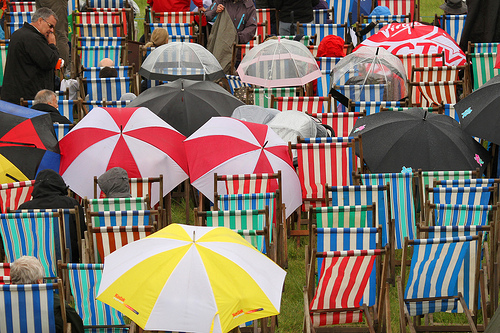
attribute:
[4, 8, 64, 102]
man — standing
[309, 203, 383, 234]
seat — green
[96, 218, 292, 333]
umbrella — white, yellow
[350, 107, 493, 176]
umbrella — black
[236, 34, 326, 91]
umbrella — clear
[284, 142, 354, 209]
chair — red, stripped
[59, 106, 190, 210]
umbrella — red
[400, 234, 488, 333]
chair — blue, stripped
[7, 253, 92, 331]
man — sitting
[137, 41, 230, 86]
umbrella — black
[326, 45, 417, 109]
umbrella — clear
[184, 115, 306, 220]
umbrella — red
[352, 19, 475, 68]
umbrella — red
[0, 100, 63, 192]
umbrella — black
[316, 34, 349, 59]
hood — red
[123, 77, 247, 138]
umbrella — grey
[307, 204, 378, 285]
chair — stripped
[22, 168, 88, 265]
jacket — black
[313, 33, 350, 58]
jacket — red